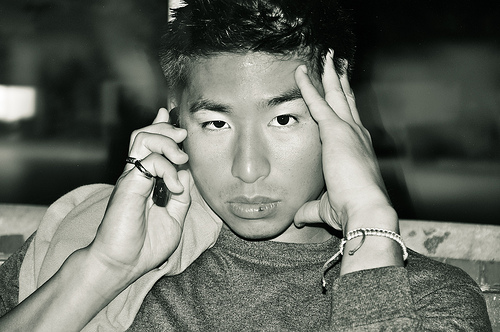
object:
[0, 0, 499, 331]
boy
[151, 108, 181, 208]
phone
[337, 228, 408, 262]
bracelet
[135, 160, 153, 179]
ring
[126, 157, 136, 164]
rings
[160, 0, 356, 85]
hair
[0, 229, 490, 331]
sweater